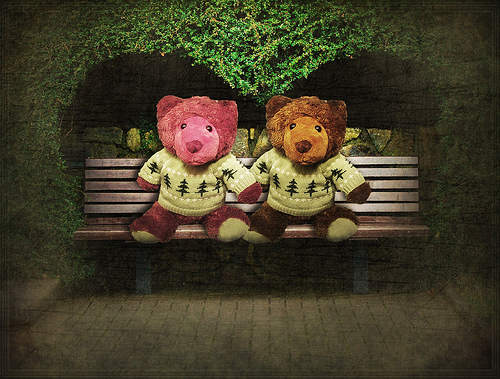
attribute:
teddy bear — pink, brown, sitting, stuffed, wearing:
[125, 93, 262, 248]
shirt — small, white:
[141, 151, 361, 212]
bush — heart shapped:
[2, 2, 499, 296]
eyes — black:
[176, 121, 216, 135]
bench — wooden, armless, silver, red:
[70, 160, 423, 247]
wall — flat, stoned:
[3, 4, 490, 298]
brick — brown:
[52, 296, 451, 367]